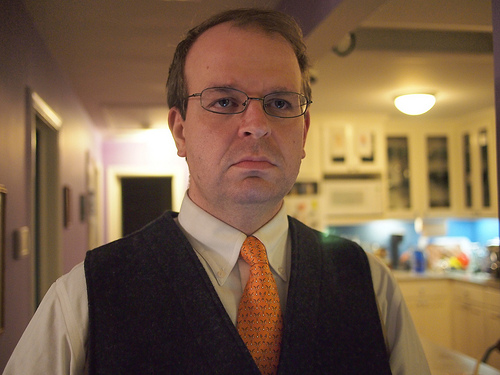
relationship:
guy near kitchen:
[0, 8, 435, 375] [262, 108, 498, 371]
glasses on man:
[170, 75, 320, 128] [30, 30, 432, 370]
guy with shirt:
[0, 8, 435, 375] [193, 212, 287, 326]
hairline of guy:
[177, 16, 307, 79] [0, 8, 435, 375]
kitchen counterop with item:
[394, 269, 492, 374] [449, 248, 476, 270]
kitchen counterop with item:
[394, 269, 492, 374] [389, 233, 411, 267]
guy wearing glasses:
[0, 8, 435, 375] [183, 79, 312, 124]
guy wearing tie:
[0, 8, 435, 375] [221, 244, 318, 348]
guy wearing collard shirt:
[0, 8, 435, 375] [0, 187, 434, 375]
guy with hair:
[0, 8, 435, 375] [238, 7, 280, 34]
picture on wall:
[301, 97, 399, 193] [35, 90, 495, 272]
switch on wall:
[12, 224, 32, 264] [0, 3, 107, 373]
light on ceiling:
[369, 74, 451, 134] [24, 0, 498, 118]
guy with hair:
[0, 8, 435, 375] [161, 2, 311, 125]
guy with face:
[0, 8, 435, 375] [189, 39, 305, 206]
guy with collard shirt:
[56, 0, 438, 373] [177, 198, 257, 335]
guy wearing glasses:
[0, 8, 435, 375] [175, 87, 312, 121]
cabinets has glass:
[384, 131, 498, 236] [385, 134, 448, 203]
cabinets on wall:
[320, 114, 386, 179] [125, 132, 159, 167]